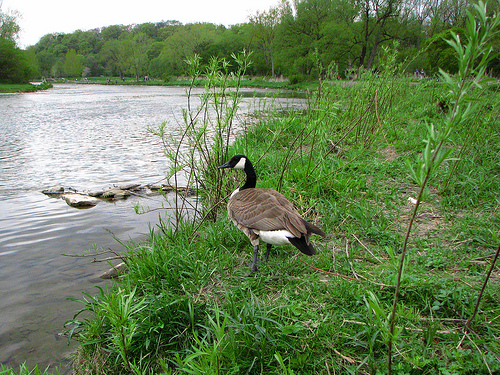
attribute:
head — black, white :
[212, 151, 261, 187]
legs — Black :
[239, 242, 282, 282]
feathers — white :
[260, 222, 309, 258]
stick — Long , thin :
[365, 115, 448, 372]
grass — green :
[82, 24, 498, 371]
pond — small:
[2, 74, 305, 374]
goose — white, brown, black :
[215, 147, 337, 282]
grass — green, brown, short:
[63, 231, 209, 352]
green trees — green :
[0, 1, 36, 88]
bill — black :
[216, 158, 230, 173]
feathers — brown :
[292, 235, 323, 258]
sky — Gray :
[2, 2, 253, 33]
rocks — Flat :
[41, 172, 199, 207]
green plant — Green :
[145, 42, 238, 215]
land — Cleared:
[327, 71, 365, 89]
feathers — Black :
[290, 234, 317, 257]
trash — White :
[402, 192, 423, 205]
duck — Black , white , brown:
[215, 153, 328, 275]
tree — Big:
[60, 47, 96, 79]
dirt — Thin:
[385, 142, 403, 163]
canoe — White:
[29, 81, 46, 89]